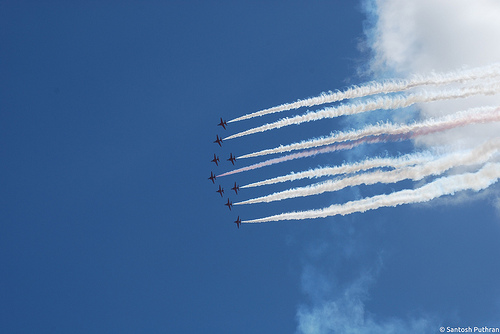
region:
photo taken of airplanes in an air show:
[159, 49, 435, 250]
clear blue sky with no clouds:
[49, 16, 135, 175]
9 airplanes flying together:
[180, 73, 285, 246]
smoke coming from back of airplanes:
[260, 75, 310, 252]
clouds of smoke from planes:
[356, 11, 454, 55]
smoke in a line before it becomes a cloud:
[263, 81, 327, 243]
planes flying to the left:
[178, 86, 283, 258]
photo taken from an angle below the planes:
[97, 49, 404, 305]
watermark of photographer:
[427, 321, 495, 329]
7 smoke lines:
[267, 90, 278, 252]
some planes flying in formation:
[201, 102, 252, 237]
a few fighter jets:
[206, 115, 247, 232]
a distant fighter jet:
[213, 114, 231, 129]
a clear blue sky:
[9, 13, 201, 315]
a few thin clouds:
[286, 250, 431, 332]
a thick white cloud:
[357, 8, 499, 63]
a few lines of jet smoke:
[257, 84, 492, 215]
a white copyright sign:
[435, 323, 447, 332]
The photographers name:
[446, 326, 498, 332]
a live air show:
[204, 100, 484, 231]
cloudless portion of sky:
[25, 87, 168, 253]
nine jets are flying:
[202, 115, 252, 233]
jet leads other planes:
[200, 166, 218, 186]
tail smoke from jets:
[227, 115, 490, 215]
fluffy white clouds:
[306, 255, 407, 330]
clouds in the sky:
[306, 241, 411, 326]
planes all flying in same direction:
[177, 102, 269, 243]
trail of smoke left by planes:
[242, 110, 487, 222]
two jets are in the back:
[220, 151, 247, 194]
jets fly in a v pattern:
[203, 113, 258, 245]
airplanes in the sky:
[205, 116, 250, 236]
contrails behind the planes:
[215, 59, 497, 225]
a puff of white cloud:
[279, 235, 466, 332]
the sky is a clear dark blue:
[0, 3, 355, 330]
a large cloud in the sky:
[365, 2, 498, 167]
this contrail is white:
[243, 162, 498, 227]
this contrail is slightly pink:
[216, 116, 498, 179]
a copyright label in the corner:
[433, 324, 498, 332]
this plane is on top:
[213, 114, 228, 133]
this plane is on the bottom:
[230, 213, 246, 231]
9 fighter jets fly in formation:
[200, 113, 250, 228]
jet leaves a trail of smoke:
[215, 69, 486, 133]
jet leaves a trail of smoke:
[225, 111, 498, 166]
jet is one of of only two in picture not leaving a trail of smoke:
[208, 151, 223, 166]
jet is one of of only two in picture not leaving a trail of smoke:
[213, 184, 225, 196]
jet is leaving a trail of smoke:
[232, 163, 498, 230]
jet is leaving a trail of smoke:
[229, 139, 499, 196]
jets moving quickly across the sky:
[206, 59, 498, 230]